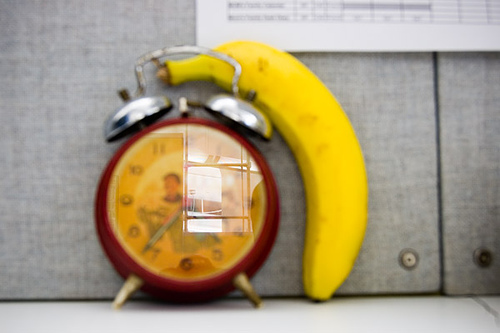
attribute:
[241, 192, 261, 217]
number — black 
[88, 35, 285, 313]
clock — round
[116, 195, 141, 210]
number — black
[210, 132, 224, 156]
number — black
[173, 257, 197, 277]
number — black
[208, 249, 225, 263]
number — black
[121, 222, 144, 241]
number — black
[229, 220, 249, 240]
number — black 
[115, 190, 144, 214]
number — black 